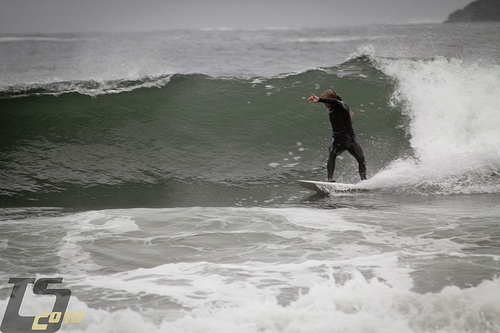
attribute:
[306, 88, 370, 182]
man — surfing, balancing, light skinned, wet, blond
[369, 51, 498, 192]
wave — large, white, crashing, big, strong, water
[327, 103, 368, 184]
wet suit — black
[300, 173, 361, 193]
surf board — white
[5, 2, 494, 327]
ocean — rough, grey, green, raging, white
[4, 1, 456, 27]
sky — gray, murky